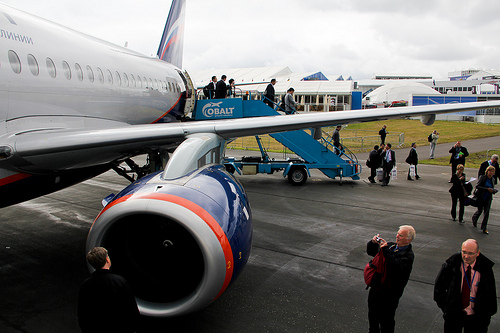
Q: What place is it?
A: It is a runway.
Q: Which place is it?
A: It is a runway.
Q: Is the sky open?
A: Yes, the sky is open.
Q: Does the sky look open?
A: Yes, the sky is open.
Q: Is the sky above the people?
A: Yes, the sky is above the people.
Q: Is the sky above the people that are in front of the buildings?
A: Yes, the sky is above the people.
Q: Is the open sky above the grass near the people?
A: Yes, the sky is above the grass.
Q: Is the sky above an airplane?
A: Yes, the sky is above an airplane.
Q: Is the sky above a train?
A: No, the sky is above an airplane.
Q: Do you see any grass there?
A: Yes, there is grass.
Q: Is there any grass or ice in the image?
A: Yes, there is grass.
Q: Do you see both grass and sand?
A: No, there is grass but no sand.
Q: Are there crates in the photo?
A: No, there are no crates.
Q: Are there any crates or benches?
A: No, there are no crates or benches.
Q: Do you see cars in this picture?
A: No, there are no cars.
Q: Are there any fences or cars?
A: No, there are no cars or fences.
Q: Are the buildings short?
A: Yes, the buildings are short.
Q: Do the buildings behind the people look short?
A: Yes, the buildings are short.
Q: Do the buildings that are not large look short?
A: Yes, the buildings are short.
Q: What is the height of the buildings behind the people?
A: The buildings are short.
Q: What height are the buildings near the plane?
A: The buildings are short.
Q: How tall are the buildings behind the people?
A: The buildings are short.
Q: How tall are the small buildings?
A: The buildings are short.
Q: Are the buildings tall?
A: No, the buildings are short.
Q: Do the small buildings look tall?
A: No, the buildings are short.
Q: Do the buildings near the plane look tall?
A: No, the buildings are short.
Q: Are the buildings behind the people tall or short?
A: The buildings are short.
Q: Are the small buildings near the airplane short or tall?
A: The buildings are short.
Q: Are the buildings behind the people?
A: Yes, the buildings are behind the people.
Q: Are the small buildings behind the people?
A: Yes, the buildings are behind the people.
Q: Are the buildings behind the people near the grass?
A: Yes, the buildings are behind the people.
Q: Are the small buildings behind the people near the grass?
A: Yes, the buildings are behind the people.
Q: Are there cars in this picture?
A: No, there are no cars.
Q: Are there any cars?
A: No, there are no cars.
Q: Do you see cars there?
A: No, there are no cars.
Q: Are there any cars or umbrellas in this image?
A: No, there are no cars or umbrellas.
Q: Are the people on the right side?
A: Yes, the people are on the right of the image.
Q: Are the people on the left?
A: No, the people are on the right of the image.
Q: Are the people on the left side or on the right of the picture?
A: The people are on the right of the image.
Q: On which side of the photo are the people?
A: The people are on the right of the image.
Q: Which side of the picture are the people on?
A: The people are on the right of the image.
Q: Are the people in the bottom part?
A: Yes, the people are in the bottom of the image.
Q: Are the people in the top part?
A: No, the people are in the bottom of the image.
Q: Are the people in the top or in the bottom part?
A: The people are in the bottom of the image.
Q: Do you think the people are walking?
A: Yes, the people are walking.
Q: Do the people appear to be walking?
A: Yes, the people are walking.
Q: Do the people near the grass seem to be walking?
A: Yes, the people are walking.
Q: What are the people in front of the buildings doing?
A: The people are walking.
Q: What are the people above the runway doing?
A: The people are walking.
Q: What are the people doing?
A: The people are walking.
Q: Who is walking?
A: The people are walking.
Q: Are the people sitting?
A: No, the people are walking.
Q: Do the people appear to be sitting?
A: No, the people are walking.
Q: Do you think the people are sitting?
A: No, the people are walking.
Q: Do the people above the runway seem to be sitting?
A: No, the people are walking.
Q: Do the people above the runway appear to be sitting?
A: No, the people are walking.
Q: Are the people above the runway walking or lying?
A: The people are walking.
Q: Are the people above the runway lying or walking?
A: The people are walking.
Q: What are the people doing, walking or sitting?
A: The people are walking.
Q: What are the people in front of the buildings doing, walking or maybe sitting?
A: The people are walking.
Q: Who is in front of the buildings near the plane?
A: The people are in front of the buildings.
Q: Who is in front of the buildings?
A: The people are in front of the buildings.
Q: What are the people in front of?
A: The people are in front of the buildings.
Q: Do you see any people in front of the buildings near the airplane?
A: Yes, there are people in front of the buildings.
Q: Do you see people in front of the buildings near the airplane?
A: Yes, there are people in front of the buildings.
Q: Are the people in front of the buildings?
A: Yes, the people are in front of the buildings.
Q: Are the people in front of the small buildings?
A: Yes, the people are in front of the buildings.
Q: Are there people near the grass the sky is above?
A: Yes, there are people near the grass.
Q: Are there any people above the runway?
A: Yes, there are people above the runway.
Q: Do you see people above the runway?
A: Yes, there are people above the runway.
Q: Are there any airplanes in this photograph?
A: Yes, there is an airplane.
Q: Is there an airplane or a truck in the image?
A: Yes, there is an airplane.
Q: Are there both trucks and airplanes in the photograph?
A: No, there is an airplane but no trucks.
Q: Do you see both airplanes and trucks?
A: No, there is an airplane but no trucks.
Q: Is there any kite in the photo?
A: No, there are no kites.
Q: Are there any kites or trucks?
A: No, there are no kites or trucks.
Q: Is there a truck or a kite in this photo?
A: No, there are no kites or trucks.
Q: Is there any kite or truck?
A: No, there are no kites or trucks.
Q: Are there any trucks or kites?
A: No, there are no kites or trucks.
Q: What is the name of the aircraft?
A: The aircraft is an airplane.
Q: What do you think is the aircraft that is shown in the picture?
A: The aircraft is an airplane.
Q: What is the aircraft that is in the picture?
A: The aircraft is an airplane.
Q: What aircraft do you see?
A: The aircraft is an airplane.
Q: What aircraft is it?
A: The aircraft is an airplane.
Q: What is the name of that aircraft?
A: This is an airplane.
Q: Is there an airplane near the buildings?
A: Yes, there is an airplane near the buildings.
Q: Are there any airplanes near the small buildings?
A: Yes, there is an airplane near the buildings.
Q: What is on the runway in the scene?
A: The plane is on the runway.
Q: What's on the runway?
A: The plane is on the runway.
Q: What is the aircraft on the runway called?
A: The aircraft is an airplane.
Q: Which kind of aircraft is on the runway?
A: The aircraft is an airplane.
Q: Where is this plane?
A: The plane is on the runway.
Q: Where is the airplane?
A: The plane is on the runway.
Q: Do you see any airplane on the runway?
A: Yes, there is an airplane on the runway.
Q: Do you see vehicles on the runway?
A: No, there is an airplane on the runway.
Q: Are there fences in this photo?
A: No, there are no fences.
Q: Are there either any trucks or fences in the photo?
A: No, there are no fences or trucks.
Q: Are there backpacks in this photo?
A: Yes, there is a backpack.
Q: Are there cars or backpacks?
A: Yes, there is a backpack.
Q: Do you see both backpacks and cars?
A: No, there is a backpack but no cars.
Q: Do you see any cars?
A: No, there are no cars.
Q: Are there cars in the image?
A: No, there are no cars.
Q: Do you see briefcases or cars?
A: No, there are no cars or briefcases.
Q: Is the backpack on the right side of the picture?
A: Yes, the backpack is on the right of the image.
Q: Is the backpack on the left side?
A: No, the backpack is on the right of the image.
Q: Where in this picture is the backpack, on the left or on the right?
A: The backpack is on the right of the image.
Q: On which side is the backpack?
A: The backpack is on the right of the image.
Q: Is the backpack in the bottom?
A: Yes, the backpack is in the bottom of the image.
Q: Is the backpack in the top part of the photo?
A: No, the backpack is in the bottom of the image.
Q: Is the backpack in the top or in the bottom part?
A: The backpack is in the bottom of the image.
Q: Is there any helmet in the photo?
A: No, there are no helmets.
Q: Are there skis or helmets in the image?
A: No, there are no helmets or skis.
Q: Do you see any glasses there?
A: No, there are no glasses.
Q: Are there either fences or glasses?
A: No, there are no glasses or fences.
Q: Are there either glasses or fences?
A: No, there are no glasses or fences.